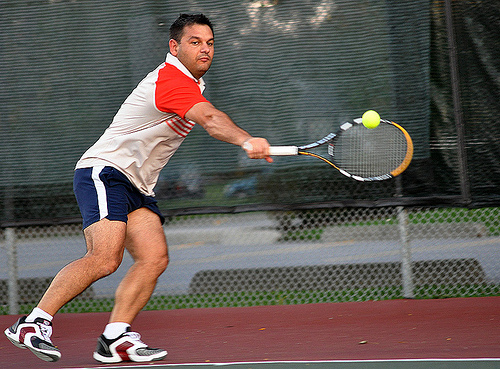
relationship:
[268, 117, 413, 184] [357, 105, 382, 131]
racket going to hit ball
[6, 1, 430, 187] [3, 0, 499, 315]
mesh hanging from fence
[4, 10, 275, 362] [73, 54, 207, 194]
man wearing shirt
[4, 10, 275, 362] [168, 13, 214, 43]
man has short hair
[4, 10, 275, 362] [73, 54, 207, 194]
man wearing a shirt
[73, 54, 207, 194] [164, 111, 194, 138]
shirt has stripes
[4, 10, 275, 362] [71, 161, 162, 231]
man wearing shorts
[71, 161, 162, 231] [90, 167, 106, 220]
shorts have a stripe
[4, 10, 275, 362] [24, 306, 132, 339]
man wearing socks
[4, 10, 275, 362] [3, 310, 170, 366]
man wearing shoes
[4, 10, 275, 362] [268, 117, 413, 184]
man holding racket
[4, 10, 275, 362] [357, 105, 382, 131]
man hitting a ball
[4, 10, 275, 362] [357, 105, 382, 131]
man hitting ball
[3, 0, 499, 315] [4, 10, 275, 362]
fence behind man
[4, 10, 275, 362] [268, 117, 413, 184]
man swinging racket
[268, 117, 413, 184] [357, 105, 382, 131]
racket about to hit ball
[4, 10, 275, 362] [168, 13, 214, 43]
man has dark hair